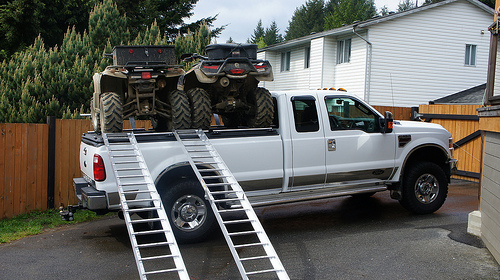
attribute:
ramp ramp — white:
[101, 129, 289, 279]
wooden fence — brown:
[3, 119, 153, 217]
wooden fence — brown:
[368, 100, 497, 183]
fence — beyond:
[413, 100, 477, 177]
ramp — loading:
[101, 122, 311, 277]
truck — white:
[49, 82, 459, 246]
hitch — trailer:
[55, 190, 101, 240]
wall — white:
[365, 1, 499, 107]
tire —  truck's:
[398, 159, 450, 213]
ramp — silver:
[168, 129, 292, 279]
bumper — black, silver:
[73, 176, 106, 208]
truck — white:
[73, 88, 458, 243]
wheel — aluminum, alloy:
[411, 173, 439, 206]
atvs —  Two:
[86, 39, 281, 131]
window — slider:
[458, 38, 495, 65]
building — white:
[242, 0, 495, 120]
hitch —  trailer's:
[57, 198, 82, 219]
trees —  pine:
[3, 27, 93, 118]